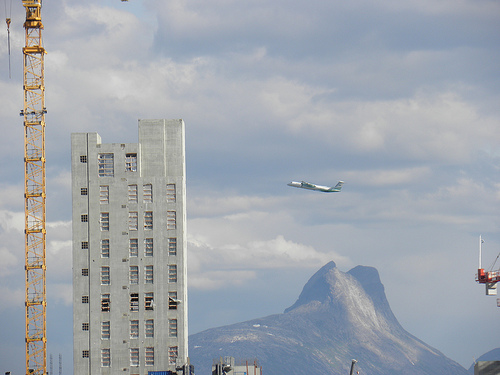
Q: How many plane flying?
A: One.